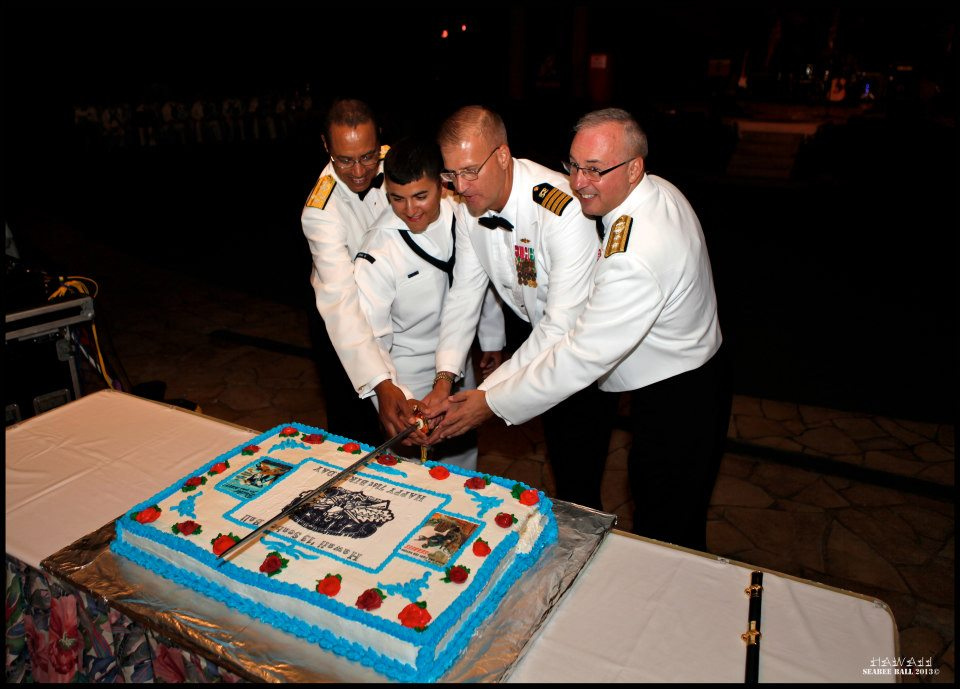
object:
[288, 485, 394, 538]
black/white image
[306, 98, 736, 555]
men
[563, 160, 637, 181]
glasses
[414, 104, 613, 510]
man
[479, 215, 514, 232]
bow tie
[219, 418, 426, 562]
knife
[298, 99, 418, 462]
man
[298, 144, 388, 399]
shirt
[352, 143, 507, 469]
man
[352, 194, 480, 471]
sailor uniform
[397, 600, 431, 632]
flower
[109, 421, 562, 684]
cake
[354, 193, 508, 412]
shirts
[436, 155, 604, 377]
shirts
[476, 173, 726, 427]
shirts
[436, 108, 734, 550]
man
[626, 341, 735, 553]
pants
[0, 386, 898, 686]
table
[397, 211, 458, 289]
tie